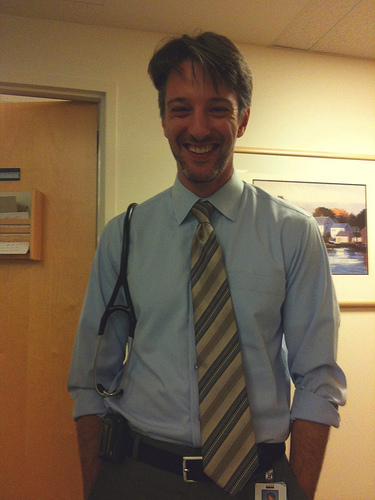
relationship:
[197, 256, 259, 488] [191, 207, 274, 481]
stripe on tie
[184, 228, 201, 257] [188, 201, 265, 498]
stripe on tie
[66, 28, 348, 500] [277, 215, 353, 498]
man has arm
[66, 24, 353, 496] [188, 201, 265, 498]
man wearing tie